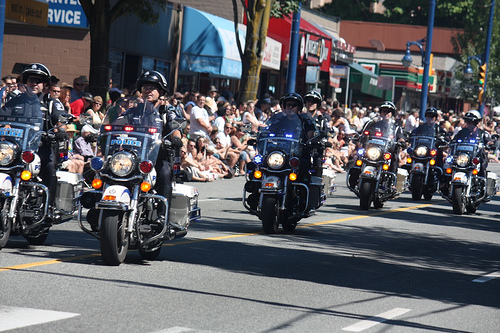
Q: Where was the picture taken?
A: It was taken at the road.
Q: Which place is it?
A: It is a road.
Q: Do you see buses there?
A: No, there are no buses.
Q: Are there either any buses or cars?
A: No, there are no buses or cars.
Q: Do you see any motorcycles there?
A: Yes, there is a motorcycle.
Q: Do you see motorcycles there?
A: Yes, there is a motorcycle.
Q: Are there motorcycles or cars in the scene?
A: Yes, there is a motorcycle.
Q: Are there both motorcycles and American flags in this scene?
A: No, there is a motorcycle but no American flags.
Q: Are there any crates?
A: No, there are no crates.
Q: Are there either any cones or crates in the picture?
A: No, there are no crates or cones.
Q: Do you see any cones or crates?
A: No, there are no crates or cones.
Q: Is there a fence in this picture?
A: No, there are no fences.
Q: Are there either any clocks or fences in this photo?
A: No, there are no fences or clocks.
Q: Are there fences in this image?
A: No, there are no fences.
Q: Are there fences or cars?
A: No, there are no fences or cars.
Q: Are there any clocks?
A: No, there are no clocks.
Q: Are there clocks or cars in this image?
A: No, there are no clocks or cars.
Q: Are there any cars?
A: No, there are no cars.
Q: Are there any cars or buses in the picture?
A: No, there are no cars or buses.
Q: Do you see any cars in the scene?
A: No, there are no cars.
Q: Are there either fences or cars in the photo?
A: No, there are no cars or fences.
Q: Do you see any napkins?
A: No, there are no napkins.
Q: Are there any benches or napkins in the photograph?
A: No, there are no napkins or benches.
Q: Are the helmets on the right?
A: Yes, the helmets are on the right of the image.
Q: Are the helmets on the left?
A: No, the helmets are on the right of the image.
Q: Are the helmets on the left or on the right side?
A: The helmets are on the right of the image.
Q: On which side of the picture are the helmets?
A: The helmets are on the right of the image.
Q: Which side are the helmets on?
A: The helmets are on the right of the image.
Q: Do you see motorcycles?
A: Yes, there is a motorcycle.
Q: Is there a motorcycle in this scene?
A: Yes, there is a motorcycle.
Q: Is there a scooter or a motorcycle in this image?
A: Yes, there is a motorcycle.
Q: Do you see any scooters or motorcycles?
A: Yes, there is a motorcycle.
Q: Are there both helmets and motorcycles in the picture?
A: Yes, there are both a motorcycle and a helmet.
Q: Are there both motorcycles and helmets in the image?
A: Yes, there are both a motorcycle and a helmet.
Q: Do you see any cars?
A: No, there are no cars.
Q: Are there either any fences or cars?
A: No, there are no cars or fences.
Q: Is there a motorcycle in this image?
A: Yes, there is a motorcycle.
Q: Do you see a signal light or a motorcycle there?
A: Yes, there is a motorcycle.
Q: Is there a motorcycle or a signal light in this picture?
A: Yes, there is a motorcycle.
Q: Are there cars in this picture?
A: No, there are no cars.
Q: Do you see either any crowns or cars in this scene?
A: No, there are no cars or crowns.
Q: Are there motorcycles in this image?
A: Yes, there is a motorcycle.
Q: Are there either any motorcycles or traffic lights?
A: Yes, there is a motorcycle.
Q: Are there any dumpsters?
A: No, there are no dumpsters.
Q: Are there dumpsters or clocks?
A: No, there are no dumpsters or clocks.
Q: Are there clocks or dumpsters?
A: No, there are no dumpsters or clocks.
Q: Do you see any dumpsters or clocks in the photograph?
A: No, there are no dumpsters or clocks.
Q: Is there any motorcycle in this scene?
A: Yes, there is a motorcycle.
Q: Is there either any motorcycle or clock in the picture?
A: Yes, there is a motorcycle.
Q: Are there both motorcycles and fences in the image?
A: No, there is a motorcycle but no fences.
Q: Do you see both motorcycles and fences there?
A: No, there is a motorcycle but no fences.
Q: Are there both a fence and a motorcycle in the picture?
A: No, there is a motorcycle but no fences.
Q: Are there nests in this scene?
A: No, there are no nests.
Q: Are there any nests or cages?
A: No, there are no nests or cages.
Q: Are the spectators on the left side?
A: Yes, the spectators are on the left of the image.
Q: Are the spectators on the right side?
A: No, the spectators are on the left of the image.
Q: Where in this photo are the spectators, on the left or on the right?
A: The spectators are on the left of the image.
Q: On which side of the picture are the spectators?
A: The spectators are on the left of the image.